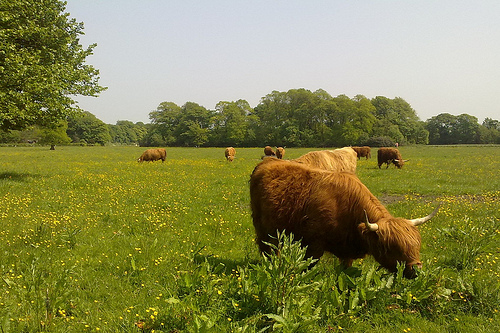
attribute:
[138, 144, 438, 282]
herd — grazing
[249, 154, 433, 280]
cow — grazing, brown, eating, shaggy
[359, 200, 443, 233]
horns — white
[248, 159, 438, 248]
fur — long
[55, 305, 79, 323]
flower — yellow, small, growing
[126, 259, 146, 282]
weed — green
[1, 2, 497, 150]
trees — distant, green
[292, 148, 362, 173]
cow — light colored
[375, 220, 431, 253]
hair — brown, long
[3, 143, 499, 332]
grass — green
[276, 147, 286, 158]
head — up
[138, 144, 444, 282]
cows — in a bunch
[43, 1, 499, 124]
sky — gray, blue, clear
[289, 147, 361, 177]
animal — light colored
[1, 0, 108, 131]
leaves — green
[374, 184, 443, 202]
dirt — gray